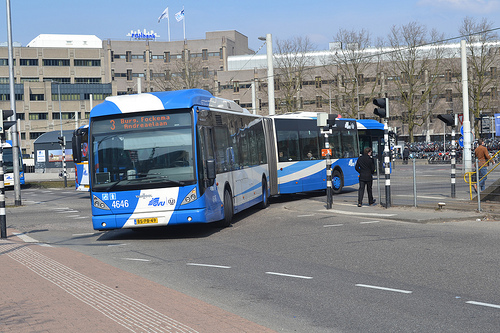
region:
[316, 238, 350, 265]
section of road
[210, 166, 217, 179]
side mirror of a bus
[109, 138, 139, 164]
wind screen of a bus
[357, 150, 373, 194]
a man walking in the streets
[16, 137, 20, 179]
section of a pole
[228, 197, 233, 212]
front wheel of a bus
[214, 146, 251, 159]
windows of a bus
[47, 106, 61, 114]
section of a brown building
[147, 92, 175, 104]
top part of a building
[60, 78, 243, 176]
Destination indicated on bus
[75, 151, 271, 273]
Bus number 4646 en route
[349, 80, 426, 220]
Standing by a traffic light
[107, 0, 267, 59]
Two flags on top of building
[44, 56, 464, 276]
Very long bus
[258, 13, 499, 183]
No leaves on the trees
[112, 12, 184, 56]
Sign on top of building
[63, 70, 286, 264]
Blue and white striped bus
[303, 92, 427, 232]
White stripes on traffic light poles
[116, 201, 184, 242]
Yellow plate on bus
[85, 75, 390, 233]
blue bus turning a corner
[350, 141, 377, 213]
person walking next to bus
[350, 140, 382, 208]
person walking next to traffic light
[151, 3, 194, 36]
flags flying on top of a building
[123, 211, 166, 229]
numberplate of the bus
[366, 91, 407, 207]
traffic light next to walking person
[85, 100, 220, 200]
front window of bus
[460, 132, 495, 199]
steps with yellow railing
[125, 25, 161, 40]
sign on top of building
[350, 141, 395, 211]
man wearing dark jacket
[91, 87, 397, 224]
long blue and white bus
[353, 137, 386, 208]
person wearing all black clothes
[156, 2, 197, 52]
2 flags on top of a building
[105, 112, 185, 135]
number 3 on bus sign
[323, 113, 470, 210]
black and white striped poles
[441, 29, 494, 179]
tall white poles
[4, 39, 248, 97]
building with lots of windows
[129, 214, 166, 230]
yellow license plate on bus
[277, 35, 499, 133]
4 trees in front of a building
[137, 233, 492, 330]
road with white stripes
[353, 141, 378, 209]
Man wearing a black suit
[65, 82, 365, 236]
Blue and white flexible bus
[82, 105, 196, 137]
Red digital display on front of bus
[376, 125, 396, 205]
Black and white pole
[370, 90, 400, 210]
traffic light on a striped pole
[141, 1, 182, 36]
Two flags flying on a rooftop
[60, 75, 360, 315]
Flexible bus making a left turn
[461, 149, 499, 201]
stairway with yellow railing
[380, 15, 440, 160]
A tree with no leaves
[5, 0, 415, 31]
A patch of blue sky